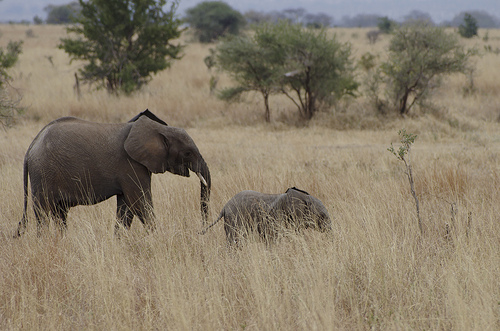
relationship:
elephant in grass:
[49, 122, 181, 195] [365, 229, 439, 294]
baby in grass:
[223, 185, 349, 239] [365, 229, 439, 294]